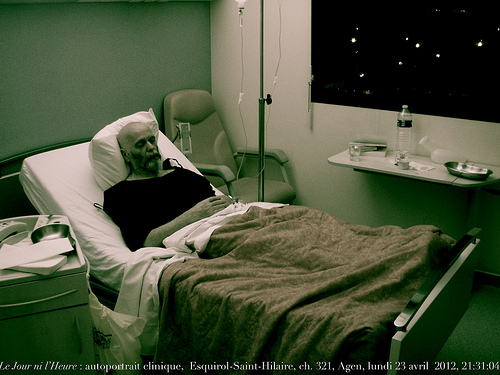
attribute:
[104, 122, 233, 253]
man — bald, laying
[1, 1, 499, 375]
hospital — in the picture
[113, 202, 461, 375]
blanket — brown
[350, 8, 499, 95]
lights — shining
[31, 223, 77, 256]
bed pan — metallic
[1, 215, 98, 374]
table — white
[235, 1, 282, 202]
tubing — in the picture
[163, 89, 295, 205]
chair — empty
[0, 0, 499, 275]
walls — white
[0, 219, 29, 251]
phone — white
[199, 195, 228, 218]
hands — folded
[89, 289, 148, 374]
plastic bag — hanging